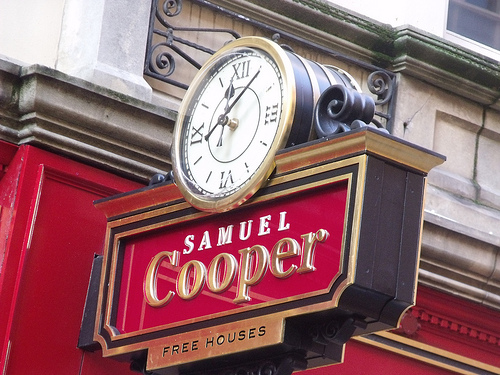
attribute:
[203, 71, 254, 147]
hand — black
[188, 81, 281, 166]
face — white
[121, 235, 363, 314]
word — gold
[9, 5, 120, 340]
building — red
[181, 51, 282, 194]
clock face — white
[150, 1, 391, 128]
iron — black, wrought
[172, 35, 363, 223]
clock — white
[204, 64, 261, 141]
hand — black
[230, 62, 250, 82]
number — black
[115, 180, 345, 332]
sign — red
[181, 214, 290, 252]
lettering — white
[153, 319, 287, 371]
sign — gold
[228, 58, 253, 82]
number — black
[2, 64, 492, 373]
building — red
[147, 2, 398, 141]
bars — black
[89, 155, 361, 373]
sign — attached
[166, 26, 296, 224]
clock — attached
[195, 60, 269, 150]
hands — black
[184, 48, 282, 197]
numerals — roman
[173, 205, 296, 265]
word — SAMUEL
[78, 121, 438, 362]
sign — large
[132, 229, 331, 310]
word — Cooper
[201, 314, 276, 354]
word — HOUSES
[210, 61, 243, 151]
hand — black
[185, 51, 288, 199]
numbers — black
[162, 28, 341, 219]
clock — round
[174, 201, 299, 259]
word — white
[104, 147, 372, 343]
sign — red